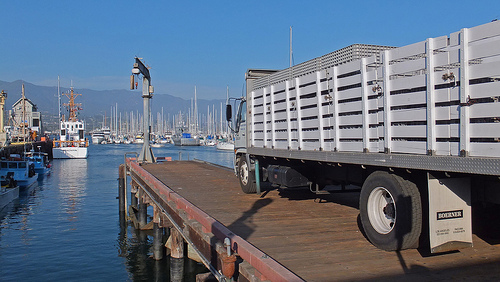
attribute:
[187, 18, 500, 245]
truck — parked, large, grey, long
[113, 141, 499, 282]
pier — steel, concrete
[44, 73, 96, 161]
boat — docked, large, white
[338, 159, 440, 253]
tire — black, large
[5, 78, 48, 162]
building — grey, two story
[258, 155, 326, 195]
gas tank — large, black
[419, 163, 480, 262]
mud flap — grey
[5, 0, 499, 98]
sky — clear, blue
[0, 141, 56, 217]
boats — docked, small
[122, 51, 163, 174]
crane — pneumatic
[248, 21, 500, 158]
paneling — grey, wooden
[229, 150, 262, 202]
tire — black, large